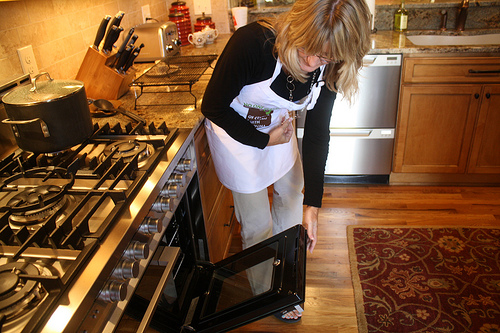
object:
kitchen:
[3, 2, 498, 329]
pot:
[2, 72, 94, 149]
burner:
[105, 135, 154, 161]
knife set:
[90, 19, 141, 69]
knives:
[91, 14, 109, 50]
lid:
[2, 69, 85, 106]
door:
[202, 241, 312, 330]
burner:
[0, 265, 48, 327]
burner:
[102, 140, 153, 165]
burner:
[22, 146, 78, 161]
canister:
[196, 13, 216, 29]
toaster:
[131, 20, 179, 62]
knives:
[103, 24, 122, 50]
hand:
[299, 206, 320, 252]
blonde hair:
[302, 15, 375, 59]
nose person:
[305, 54, 321, 67]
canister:
[169, 2, 191, 47]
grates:
[6, 167, 69, 223]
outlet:
[15, 45, 39, 81]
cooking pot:
[0, 70, 94, 153]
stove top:
[0, 120, 178, 332]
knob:
[121, 239, 150, 261]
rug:
[347, 224, 499, 332]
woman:
[200, 0, 369, 321]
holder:
[72, 45, 133, 99]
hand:
[264, 116, 296, 148]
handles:
[0, 116, 51, 138]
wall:
[1, 2, 173, 92]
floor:
[211, 186, 498, 331]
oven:
[0, 120, 309, 330]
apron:
[201, 24, 328, 193]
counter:
[82, 29, 237, 132]